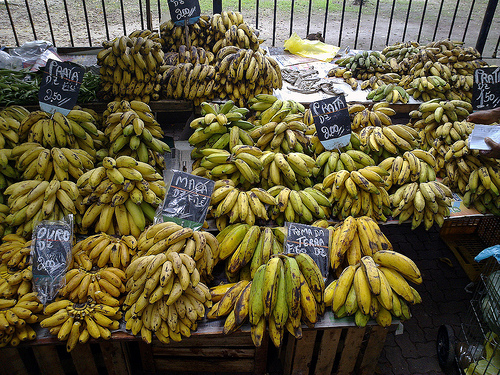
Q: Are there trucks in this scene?
A: No, there are no trucks.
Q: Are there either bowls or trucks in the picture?
A: No, there are no trucks or bowls.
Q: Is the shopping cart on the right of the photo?
A: Yes, the shopping cart is on the right of the image.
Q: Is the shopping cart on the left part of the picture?
A: No, the shopping cart is on the right of the image.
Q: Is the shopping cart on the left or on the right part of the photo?
A: The shopping cart is on the right of the image.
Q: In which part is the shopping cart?
A: The shopping cart is on the right of the image.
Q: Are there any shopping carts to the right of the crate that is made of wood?
A: Yes, there is a shopping cart to the right of the crate.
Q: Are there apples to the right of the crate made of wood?
A: No, there is a shopping cart to the right of the crate.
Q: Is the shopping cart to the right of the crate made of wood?
A: Yes, the shopping cart is to the right of the crate.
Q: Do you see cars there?
A: No, there are no cars.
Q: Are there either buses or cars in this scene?
A: No, there are no cars or buses.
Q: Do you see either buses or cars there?
A: No, there are no cars or buses.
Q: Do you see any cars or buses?
A: No, there are no cars or buses.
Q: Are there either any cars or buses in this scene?
A: No, there are no cars or buses.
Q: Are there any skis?
A: No, there are no skis.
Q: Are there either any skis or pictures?
A: No, there are no skis or pictures.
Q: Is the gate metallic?
A: Yes, the gate is metallic.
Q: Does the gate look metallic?
A: Yes, the gate is metallic.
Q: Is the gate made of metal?
A: Yes, the gate is made of metal.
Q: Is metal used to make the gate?
A: Yes, the gate is made of metal.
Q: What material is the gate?
A: The gate is made of metal.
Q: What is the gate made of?
A: The gate is made of metal.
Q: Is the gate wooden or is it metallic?
A: The gate is metallic.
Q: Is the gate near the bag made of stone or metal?
A: The gate is made of metal.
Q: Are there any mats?
A: No, there are no mats.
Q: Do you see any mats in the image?
A: No, there are no mats.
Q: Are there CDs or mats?
A: No, there are no mats or cds.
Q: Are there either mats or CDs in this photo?
A: No, there are no mats or cds.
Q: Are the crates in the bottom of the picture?
A: Yes, the crates are in the bottom of the image.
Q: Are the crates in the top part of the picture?
A: No, the crates are in the bottom of the image.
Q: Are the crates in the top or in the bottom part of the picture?
A: The crates are in the bottom of the image.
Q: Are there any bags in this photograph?
A: Yes, there is a bag.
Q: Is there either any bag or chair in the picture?
A: Yes, there is a bag.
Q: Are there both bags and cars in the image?
A: No, there is a bag but no cars.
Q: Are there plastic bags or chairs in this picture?
A: Yes, there is a plastic bag.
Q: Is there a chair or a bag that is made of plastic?
A: Yes, the bag is made of plastic.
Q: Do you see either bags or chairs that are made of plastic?
A: Yes, the bag is made of plastic.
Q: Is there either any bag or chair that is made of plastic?
A: Yes, the bag is made of plastic.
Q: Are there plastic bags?
A: Yes, there is a bag that is made of plastic.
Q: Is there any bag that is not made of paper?
A: Yes, there is a bag that is made of plastic.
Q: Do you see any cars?
A: No, there are no cars.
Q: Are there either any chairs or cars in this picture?
A: No, there are no cars or chairs.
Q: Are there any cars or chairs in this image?
A: No, there are no cars or chairs.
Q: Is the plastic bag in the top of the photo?
A: Yes, the bag is in the top of the image.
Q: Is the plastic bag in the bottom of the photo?
A: No, the bag is in the top of the image.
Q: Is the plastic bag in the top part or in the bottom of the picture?
A: The bag is in the top of the image.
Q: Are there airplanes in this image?
A: No, there are no airplanes.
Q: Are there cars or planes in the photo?
A: No, there are no planes or cars.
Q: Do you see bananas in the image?
A: Yes, there is a banana.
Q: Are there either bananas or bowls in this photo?
A: Yes, there is a banana.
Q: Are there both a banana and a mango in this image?
A: No, there is a banana but no mangoes.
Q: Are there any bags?
A: Yes, there is a bag.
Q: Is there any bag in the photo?
A: Yes, there is a bag.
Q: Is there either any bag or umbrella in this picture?
A: Yes, there is a bag.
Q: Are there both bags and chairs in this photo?
A: No, there is a bag but no chairs.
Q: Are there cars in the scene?
A: No, there are no cars.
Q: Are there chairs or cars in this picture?
A: No, there are no cars or chairs.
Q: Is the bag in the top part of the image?
A: Yes, the bag is in the top of the image.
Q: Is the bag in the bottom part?
A: No, the bag is in the top of the image.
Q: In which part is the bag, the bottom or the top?
A: The bag is in the top of the image.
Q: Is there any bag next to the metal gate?
A: Yes, there is a bag next to the gate.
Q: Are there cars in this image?
A: No, there are no cars.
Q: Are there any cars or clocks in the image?
A: No, there are no cars or clocks.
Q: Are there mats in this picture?
A: No, there are no mats.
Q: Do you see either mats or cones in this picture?
A: No, there are no mats or cones.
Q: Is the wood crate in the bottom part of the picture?
A: Yes, the crate is in the bottom of the image.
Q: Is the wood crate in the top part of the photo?
A: No, the crate is in the bottom of the image.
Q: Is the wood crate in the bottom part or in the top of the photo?
A: The crate is in the bottom of the image.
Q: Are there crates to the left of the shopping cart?
A: Yes, there is a crate to the left of the shopping cart.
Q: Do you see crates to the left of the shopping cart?
A: Yes, there is a crate to the left of the shopping cart.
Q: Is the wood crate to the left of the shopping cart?
A: Yes, the crate is to the left of the shopping cart.